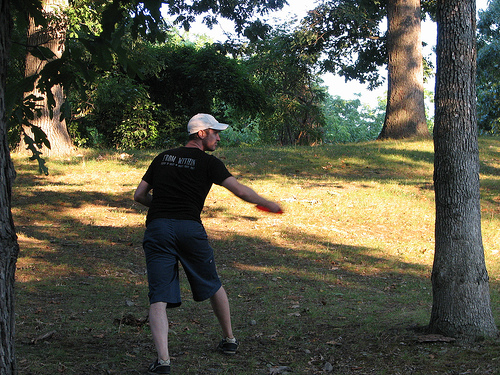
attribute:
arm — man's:
[212, 168, 303, 219]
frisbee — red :
[253, 201, 284, 216]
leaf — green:
[127, 57, 138, 75]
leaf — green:
[104, 87, 114, 107]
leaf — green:
[135, 122, 150, 137]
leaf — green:
[187, 64, 201, 84]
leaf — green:
[213, 71, 225, 85]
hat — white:
[186, 111, 228, 138]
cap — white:
[182, 105, 233, 140]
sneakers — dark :
[140, 335, 243, 373]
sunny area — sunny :
[297, 176, 442, 243]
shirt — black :
[139, 144, 234, 219]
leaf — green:
[119, 51, 137, 67]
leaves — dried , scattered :
[90, 331, 103, 341]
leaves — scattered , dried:
[326, 337, 338, 344]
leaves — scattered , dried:
[266, 359, 289, 373]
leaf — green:
[149, 69, 177, 91]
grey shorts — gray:
[128, 224, 243, 316]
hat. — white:
[173, 102, 238, 148]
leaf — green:
[194, 54, 233, 94]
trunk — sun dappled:
[371, 26, 473, 134]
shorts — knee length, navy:
[144, 218, 228, 317]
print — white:
[160, 152, 197, 170]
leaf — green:
[255, 51, 262, 56]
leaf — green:
[258, 56, 265, 61]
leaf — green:
[258, 55, 266, 62]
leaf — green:
[270, 48, 277, 53]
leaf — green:
[265, 84, 270, 89]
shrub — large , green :
[96, 46, 263, 113]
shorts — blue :
[141, 217, 223, 307]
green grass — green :
[1, 131, 498, 187]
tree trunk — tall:
[437, 35, 490, 344]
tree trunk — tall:
[389, 10, 429, 142]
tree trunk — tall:
[10, 13, 84, 163]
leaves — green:
[121, 20, 273, 104]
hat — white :
[183, 108, 239, 134]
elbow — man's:
[128, 185, 149, 208]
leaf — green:
[134, 130, 140, 135]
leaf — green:
[139, 104, 143, 111]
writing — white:
[163, 151, 199, 172]